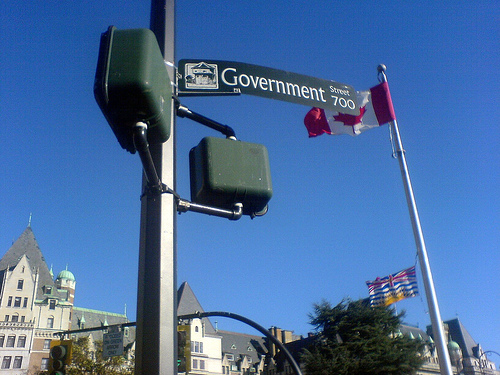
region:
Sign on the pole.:
[158, 39, 415, 162]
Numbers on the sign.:
[316, 73, 381, 142]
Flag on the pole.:
[223, 209, 438, 318]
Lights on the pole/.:
[41, 17, 343, 287]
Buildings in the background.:
[6, 213, 100, 368]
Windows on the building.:
[10, 266, 77, 369]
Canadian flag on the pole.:
[269, 69, 481, 174]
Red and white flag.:
[312, 64, 437, 177]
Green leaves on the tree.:
[261, 288, 371, 363]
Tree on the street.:
[296, 290, 382, 360]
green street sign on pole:
[180, 55, 360, 114]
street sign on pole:
[176, 60, 358, 114]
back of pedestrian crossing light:
[191, 137, 282, 209]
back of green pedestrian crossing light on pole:
[188, 137, 270, 203]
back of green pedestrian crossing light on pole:
[103, 25, 177, 140]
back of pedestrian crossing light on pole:
[108, 25, 168, 147]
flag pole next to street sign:
[376, 62, 461, 373]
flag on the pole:
[301, 83, 394, 133]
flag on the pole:
[353, 268, 435, 310]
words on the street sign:
[222, 64, 333, 114]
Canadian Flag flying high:
[302, 84, 395, 141]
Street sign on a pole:
[177, 59, 359, 118]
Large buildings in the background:
[0, 212, 496, 374]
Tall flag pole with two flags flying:
[304, 61, 470, 373]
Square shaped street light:
[95, 26, 173, 193]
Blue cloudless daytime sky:
[0, 1, 497, 359]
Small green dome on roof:
[57, 264, 74, 279]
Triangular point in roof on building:
[177, 282, 219, 334]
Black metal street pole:
[134, 0, 177, 372]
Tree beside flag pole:
[300, 292, 428, 374]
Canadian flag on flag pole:
[302, 81, 395, 136]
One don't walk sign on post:
[184, 129, 274, 221]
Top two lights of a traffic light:
[46, 331, 68, 373]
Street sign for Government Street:
[177, 54, 372, 114]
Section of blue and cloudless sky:
[6, 40, 90, 202]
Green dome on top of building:
[57, 261, 77, 281]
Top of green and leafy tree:
[300, 288, 427, 372]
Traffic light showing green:
[174, 321, 189, 371]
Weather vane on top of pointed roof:
[22, 205, 36, 230]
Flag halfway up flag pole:
[357, 238, 433, 316]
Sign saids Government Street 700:
[181, 46, 386, 118]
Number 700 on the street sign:
[324, 91, 374, 123]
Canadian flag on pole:
[284, 69, 414, 151]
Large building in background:
[12, 228, 497, 373]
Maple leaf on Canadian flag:
[322, 89, 378, 139]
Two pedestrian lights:
[90, 28, 293, 230]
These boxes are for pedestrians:
[72, 16, 292, 211]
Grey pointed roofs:
[7, 222, 242, 352]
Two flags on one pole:
[315, 79, 435, 329]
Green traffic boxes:
[82, 28, 275, 219]